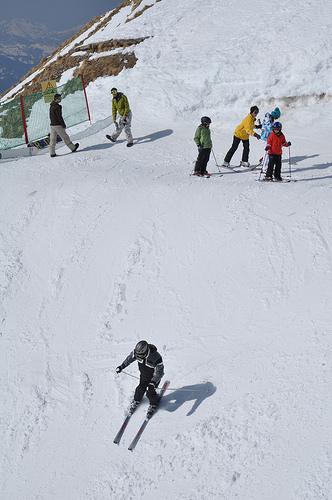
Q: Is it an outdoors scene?
A: Yes, it is outdoors.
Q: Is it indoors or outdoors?
A: It is outdoors.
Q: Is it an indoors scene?
A: No, it is outdoors.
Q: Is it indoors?
A: No, it is outdoors.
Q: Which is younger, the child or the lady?
A: The child is younger than the lady.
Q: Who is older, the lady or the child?
A: The lady is older than the child.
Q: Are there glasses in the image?
A: No, there are no glasses.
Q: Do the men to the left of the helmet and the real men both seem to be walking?
A: Yes, both the men and the men are walking.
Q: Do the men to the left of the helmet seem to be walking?
A: Yes, the men are walking.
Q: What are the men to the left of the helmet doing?
A: The men are walking.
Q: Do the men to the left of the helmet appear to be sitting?
A: No, the men are walking.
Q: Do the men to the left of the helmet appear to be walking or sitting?
A: The men are walking.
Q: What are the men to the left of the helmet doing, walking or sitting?
A: The men are walking.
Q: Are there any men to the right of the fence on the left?
A: Yes, there are men to the right of the fence.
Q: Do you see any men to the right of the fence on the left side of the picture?
A: Yes, there are men to the right of the fence.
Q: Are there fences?
A: Yes, there is a fence.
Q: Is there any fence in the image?
A: Yes, there is a fence.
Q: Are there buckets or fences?
A: Yes, there is a fence.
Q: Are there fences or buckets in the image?
A: Yes, there is a fence.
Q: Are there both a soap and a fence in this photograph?
A: No, there is a fence but no soaps.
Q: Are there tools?
A: No, there are no tools.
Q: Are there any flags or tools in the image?
A: No, there are no tools or flags.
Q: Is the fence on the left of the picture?
A: Yes, the fence is on the left of the image.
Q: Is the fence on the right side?
A: No, the fence is on the left of the image.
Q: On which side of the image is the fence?
A: The fence is on the left of the image.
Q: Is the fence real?
A: Yes, the fence is real.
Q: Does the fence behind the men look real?
A: Yes, the fence is real.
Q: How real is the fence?
A: The fence is real.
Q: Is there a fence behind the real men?
A: Yes, there is a fence behind the men.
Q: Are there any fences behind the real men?
A: Yes, there is a fence behind the men.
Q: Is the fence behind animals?
A: No, the fence is behind the men.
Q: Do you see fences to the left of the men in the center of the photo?
A: Yes, there is a fence to the left of the men.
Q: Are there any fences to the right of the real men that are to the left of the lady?
A: No, the fence is to the left of the men.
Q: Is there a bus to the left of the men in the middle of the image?
A: No, there is a fence to the left of the men.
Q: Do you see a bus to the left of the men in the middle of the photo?
A: No, there is a fence to the left of the men.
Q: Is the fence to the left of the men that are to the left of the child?
A: Yes, the fence is to the left of the men.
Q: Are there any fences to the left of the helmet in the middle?
A: Yes, there is a fence to the left of the helmet.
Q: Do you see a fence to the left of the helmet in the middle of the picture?
A: Yes, there is a fence to the left of the helmet.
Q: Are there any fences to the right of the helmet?
A: No, the fence is to the left of the helmet.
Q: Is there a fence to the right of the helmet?
A: No, the fence is to the left of the helmet.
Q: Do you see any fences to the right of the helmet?
A: No, the fence is to the left of the helmet.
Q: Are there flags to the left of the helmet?
A: No, there is a fence to the left of the helmet.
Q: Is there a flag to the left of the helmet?
A: No, there is a fence to the left of the helmet.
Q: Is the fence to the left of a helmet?
A: Yes, the fence is to the left of a helmet.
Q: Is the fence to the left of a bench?
A: No, the fence is to the left of a helmet.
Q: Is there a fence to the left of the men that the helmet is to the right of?
A: Yes, there is a fence to the left of the men.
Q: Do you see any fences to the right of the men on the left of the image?
A: No, the fence is to the left of the men.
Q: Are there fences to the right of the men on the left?
A: No, the fence is to the left of the men.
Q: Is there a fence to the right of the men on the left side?
A: No, the fence is to the left of the men.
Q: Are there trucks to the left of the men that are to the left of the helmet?
A: No, there is a fence to the left of the men.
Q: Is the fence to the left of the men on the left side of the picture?
A: Yes, the fence is to the left of the men.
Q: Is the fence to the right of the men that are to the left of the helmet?
A: No, the fence is to the left of the men.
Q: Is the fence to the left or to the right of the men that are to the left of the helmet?
A: The fence is to the left of the men.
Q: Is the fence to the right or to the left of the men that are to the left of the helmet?
A: The fence is to the left of the men.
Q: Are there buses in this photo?
A: No, there are no buses.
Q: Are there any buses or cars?
A: No, there are no buses or cars.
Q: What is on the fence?
A: The sign is on the fence.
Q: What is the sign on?
A: The sign is on the fence.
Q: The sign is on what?
A: The sign is on the fence.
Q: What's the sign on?
A: The sign is on the fence.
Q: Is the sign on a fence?
A: Yes, the sign is on a fence.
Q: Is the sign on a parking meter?
A: No, the sign is on a fence.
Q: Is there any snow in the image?
A: Yes, there is snow.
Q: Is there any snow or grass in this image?
A: Yes, there is snow.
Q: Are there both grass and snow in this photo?
A: No, there is snow but no grass.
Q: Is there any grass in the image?
A: No, there is no grass.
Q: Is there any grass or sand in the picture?
A: No, there are no grass or sand.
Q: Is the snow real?
A: Yes, the snow is real.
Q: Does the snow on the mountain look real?
A: Yes, the snow is real.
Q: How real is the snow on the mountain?
A: The snow is real.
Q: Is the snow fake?
A: No, the snow is real.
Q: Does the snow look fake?
A: No, the snow is real.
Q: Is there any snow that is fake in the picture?
A: No, there is snow but it is real.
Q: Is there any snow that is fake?
A: No, there is snow but it is real.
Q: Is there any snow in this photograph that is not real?
A: No, there is snow but it is real.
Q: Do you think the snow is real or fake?
A: The snow is real.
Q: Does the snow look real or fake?
A: The snow is real.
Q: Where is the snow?
A: The snow is on the mountain.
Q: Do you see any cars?
A: No, there are no cars.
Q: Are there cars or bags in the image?
A: No, there are no cars or bags.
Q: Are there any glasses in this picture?
A: No, there are no glasses.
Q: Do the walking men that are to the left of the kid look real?
A: Yes, the men are real.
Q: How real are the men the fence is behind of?
A: The men are real.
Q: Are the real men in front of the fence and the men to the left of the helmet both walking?
A: Yes, both the men and the men are walking.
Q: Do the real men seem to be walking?
A: Yes, the men are walking.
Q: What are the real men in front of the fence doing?
A: The men are walking.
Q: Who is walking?
A: The men are walking.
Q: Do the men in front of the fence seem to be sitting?
A: No, the men are walking.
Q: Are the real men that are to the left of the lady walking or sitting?
A: The men are walking.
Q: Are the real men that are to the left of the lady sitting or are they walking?
A: The men are walking.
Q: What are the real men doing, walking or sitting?
A: The men are walking.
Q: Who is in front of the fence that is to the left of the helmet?
A: The men are in front of the fence.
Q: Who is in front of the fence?
A: The men are in front of the fence.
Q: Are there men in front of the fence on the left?
A: Yes, there are men in front of the fence.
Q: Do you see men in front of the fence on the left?
A: Yes, there are men in front of the fence.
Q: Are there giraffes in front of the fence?
A: No, there are men in front of the fence.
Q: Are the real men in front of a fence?
A: Yes, the men are in front of a fence.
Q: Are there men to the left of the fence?
A: No, the men are to the right of the fence.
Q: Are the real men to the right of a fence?
A: Yes, the men are to the right of a fence.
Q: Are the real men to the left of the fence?
A: No, the men are to the right of the fence.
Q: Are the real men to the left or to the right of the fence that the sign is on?
A: The men are to the right of the fence.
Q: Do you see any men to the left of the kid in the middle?
A: Yes, there are men to the left of the kid.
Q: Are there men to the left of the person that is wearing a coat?
A: Yes, there are men to the left of the kid.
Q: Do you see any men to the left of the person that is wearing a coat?
A: Yes, there are men to the left of the kid.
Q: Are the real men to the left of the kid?
A: Yes, the men are to the left of the kid.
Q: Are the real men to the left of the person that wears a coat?
A: Yes, the men are to the left of the kid.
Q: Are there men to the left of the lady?
A: Yes, there are men to the left of the lady.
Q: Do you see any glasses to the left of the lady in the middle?
A: No, there are men to the left of the lady.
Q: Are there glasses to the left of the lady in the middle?
A: No, there are men to the left of the lady.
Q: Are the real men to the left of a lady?
A: Yes, the men are to the left of a lady.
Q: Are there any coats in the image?
A: Yes, there is a coat.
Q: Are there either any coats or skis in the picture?
A: Yes, there is a coat.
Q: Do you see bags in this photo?
A: No, there are no bags.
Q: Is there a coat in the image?
A: Yes, there is a coat.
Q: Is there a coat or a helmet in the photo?
A: Yes, there is a coat.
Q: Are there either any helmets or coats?
A: Yes, there is a coat.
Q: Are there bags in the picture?
A: No, there are no bags.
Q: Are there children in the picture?
A: Yes, there is a child.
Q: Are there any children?
A: Yes, there is a child.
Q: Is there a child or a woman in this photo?
A: Yes, there is a child.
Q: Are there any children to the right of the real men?
A: Yes, there is a child to the right of the men.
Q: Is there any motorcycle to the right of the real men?
A: No, there is a child to the right of the men.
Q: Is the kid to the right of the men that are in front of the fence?
A: Yes, the kid is to the right of the men.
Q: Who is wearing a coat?
A: The kid is wearing a coat.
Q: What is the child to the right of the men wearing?
A: The kid is wearing a coat.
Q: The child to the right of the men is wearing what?
A: The kid is wearing a coat.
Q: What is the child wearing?
A: The kid is wearing a coat.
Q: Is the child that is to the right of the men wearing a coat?
A: Yes, the kid is wearing a coat.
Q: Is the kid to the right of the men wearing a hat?
A: No, the kid is wearing a coat.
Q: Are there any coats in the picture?
A: Yes, there is a coat.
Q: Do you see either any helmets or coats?
A: Yes, there is a coat.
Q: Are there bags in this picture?
A: No, there are no bags.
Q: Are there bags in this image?
A: No, there are no bags.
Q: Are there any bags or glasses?
A: No, there are no bags or glasses.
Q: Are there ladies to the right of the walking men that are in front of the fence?
A: Yes, there is a lady to the right of the men.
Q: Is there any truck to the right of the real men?
A: No, there is a lady to the right of the men.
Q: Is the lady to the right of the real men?
A: Yes, the lady is to the right of the men.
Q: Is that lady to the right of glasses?
A: No, the lady is to the right of the men.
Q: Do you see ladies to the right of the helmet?
A: Yes, there is a lady to the right of the helmet.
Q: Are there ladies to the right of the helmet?
A: Yes, there is a lady to the right of the helmet.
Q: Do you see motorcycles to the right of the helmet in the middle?
A: No, there is a lady to the right of the helmet.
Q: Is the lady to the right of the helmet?
A: Yes, the lady is to the right of the helmet.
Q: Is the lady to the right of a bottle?
A: No, the lady is to the right of the helmet.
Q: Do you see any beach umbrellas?
A: No, there are no beach umbrellas.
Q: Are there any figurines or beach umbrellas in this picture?
A: No, there are no beach umbrellas or figurines.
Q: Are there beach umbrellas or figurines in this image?
A: No, there are no beach umbrellas or figurines.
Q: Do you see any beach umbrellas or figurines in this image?
A: No, there are no beach umbrellas or figurines.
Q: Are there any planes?
A: No, there are no planes.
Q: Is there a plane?
A: No, there are no airplanes.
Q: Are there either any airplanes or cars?
A: No, there are no airplanes or cars.